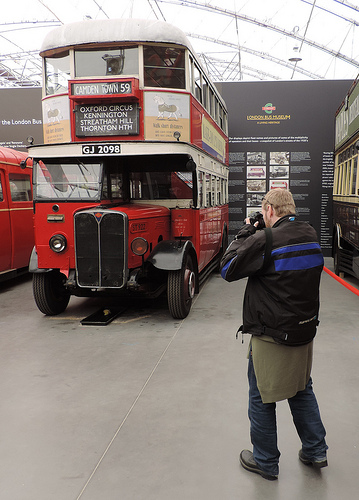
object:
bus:
[28, 16, 229, 320]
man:
[218, 187, 327, 478]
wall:
[0, 78, 359, 258]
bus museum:
[0, 0, 358, 498]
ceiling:
[0, 1, 359, 86]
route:
[78, 105, 134, 134]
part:
[0, 142, 41, 275]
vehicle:
[0, 143, 41, 282]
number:
[97, 143, 103, 155]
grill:
[74, 209, 99, 286]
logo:
[260, 100, 275, 116]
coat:
[220, 210, 322, 347]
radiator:
[99, 210, 126, 286]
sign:
[261, 100, 277, 113]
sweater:
[250, 335, 313, 404]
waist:
[252, 306, 319, 348]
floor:
[2, 253, 358, 499]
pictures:
[245, 150, 266, 167]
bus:
[331, 73, 358, 295]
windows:
[350, 154, 358, 195]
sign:
[143, 90, 192, 140]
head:
[260, 186, 294, 231]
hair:
[261, 189, 297, 223]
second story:
[38, 18, 230, 164]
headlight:
[129, 236, 151, 258]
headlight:
[48, 232, 70, 255]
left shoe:
[239, 447, 284, 481]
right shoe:
[297, 448, 326, 467]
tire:
[167, 254, 197, 321]